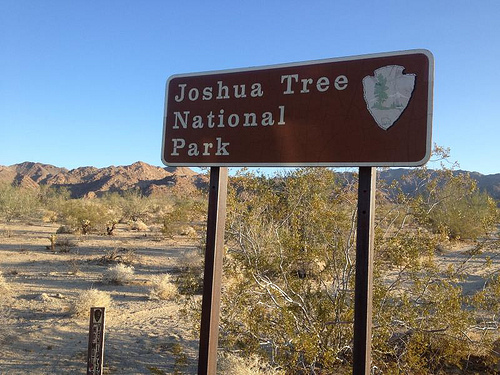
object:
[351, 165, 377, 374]
metal post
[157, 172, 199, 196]
hills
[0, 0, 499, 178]
blue sky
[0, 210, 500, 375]
ground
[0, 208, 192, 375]
sand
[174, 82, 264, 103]
joshua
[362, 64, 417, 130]
map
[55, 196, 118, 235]
shrubs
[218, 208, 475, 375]
tree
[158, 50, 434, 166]
park sign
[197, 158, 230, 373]
brown stand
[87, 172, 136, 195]
hills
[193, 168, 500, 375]
bush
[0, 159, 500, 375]
park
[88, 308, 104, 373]
post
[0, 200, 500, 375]
land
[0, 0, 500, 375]
photo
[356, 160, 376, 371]
metal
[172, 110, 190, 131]
letters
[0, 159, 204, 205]
mountain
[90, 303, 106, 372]
thermometer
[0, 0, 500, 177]
sky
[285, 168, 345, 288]
tree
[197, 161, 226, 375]
post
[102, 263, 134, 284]
plant